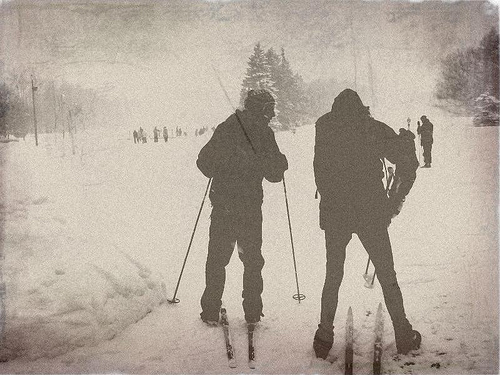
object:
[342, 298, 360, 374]
skis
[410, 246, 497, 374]
snow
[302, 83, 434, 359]
person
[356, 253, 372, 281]
ski poles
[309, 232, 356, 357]
leg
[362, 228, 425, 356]
leg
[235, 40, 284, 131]
trees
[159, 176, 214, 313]
ski pole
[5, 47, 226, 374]
snow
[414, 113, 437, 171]
man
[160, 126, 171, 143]
people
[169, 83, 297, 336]
man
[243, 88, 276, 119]
hat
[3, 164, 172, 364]
snow bank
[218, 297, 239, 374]
skis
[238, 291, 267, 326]
feet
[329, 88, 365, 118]
hood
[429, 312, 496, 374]
marks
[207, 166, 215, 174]
hand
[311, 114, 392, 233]
back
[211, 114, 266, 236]
back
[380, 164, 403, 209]
ski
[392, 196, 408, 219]
hand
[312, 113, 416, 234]
jacket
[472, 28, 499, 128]
tree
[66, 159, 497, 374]
ground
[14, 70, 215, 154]
background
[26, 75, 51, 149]
pole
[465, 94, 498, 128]
bush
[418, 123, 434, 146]
cloth